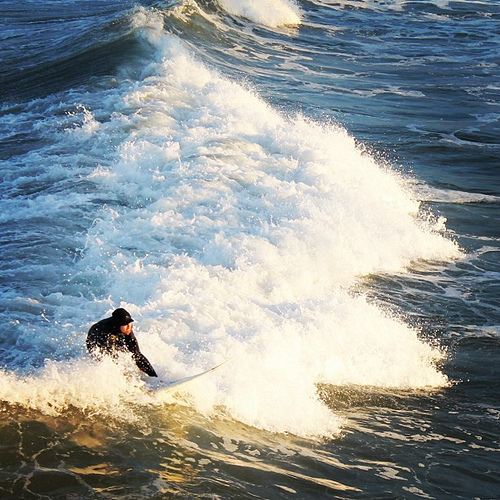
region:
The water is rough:
[65, 38, 427, 415]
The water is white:
[87, 72, 442, 432]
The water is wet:
[50, 76, 429, 421]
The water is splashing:
[49, 65, 409, 417]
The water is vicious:
[78, 23, 365, 335]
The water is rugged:
[33, 60, 440, 416]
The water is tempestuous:
[53, 48, 440, 415]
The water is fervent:
[34, 89, 422, 414]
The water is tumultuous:
[26, 45, 411, 388]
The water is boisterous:
[71, 65, 414, 367]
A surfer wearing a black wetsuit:
[86, 306, 226, 403]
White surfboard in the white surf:
[139, 360, 226, 397]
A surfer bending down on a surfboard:
[86, 306, 233, 396]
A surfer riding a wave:
[84, 305, 226, 394]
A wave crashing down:
[209, 162, 455, 436]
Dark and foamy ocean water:
[138, 420, 384, 493]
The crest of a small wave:
[111, 0, 211, 72]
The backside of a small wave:
[0, 4, 137, 74]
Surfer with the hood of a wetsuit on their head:
[108, 306, 133, 338]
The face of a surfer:
[118, 317, 134, 339]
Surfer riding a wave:
[83, 307, 223, 397]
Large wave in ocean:
[7, 0, 463, 444]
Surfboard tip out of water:
[148, 361, 226, 399]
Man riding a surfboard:
[83, 308, 220, 388]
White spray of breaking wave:
[6, 3, 448, 438]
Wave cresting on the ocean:
[17, 0, 464, 445]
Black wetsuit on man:
[86, 309, 156, 384]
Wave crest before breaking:
[105, 4, 256, 47]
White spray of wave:
[190, 43, 457, 239]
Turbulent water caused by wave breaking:
[7, 60, 457, 442]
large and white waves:
[60, 53, 350, 388]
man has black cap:
[99, 293, 154, 338]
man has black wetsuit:
[90, 313, 157, 385]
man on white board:
[137, 363, 244, 395]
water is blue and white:
[263, 60, 432, 135]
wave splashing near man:
[12, 360, 111, 413]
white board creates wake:
[22, 345, 142, 412]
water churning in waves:
[154, 143, 374, 324]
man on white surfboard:
[149, 353, 215, 386]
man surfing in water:
[76, 292, 284, 421]